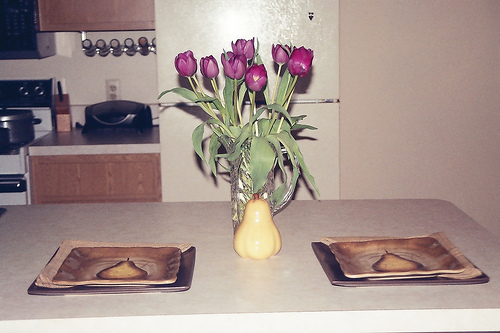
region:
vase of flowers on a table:
[166, 30, 318, 190]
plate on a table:
[301, 196, 491, 301]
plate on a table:
[30, 220, 208, 306]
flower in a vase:
[283, 35, 313, 85]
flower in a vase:
[246, 58, 271, 88]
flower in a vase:
[221, 46, 244, 84]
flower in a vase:
[195, 47, 225, 82]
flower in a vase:
[166, 45, 192, 75]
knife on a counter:
[45, 76, 72, 146]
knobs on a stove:
[11, 80, 49, 105]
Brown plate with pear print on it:
[34, 237, 196, 294]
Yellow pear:
[226, 190, 291, 259]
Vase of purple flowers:
[160, 31, 316, 257]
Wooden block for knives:
[53, 79, 75, 130]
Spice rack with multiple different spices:
[76, 28, 156, 55]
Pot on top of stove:
[0, 100, 41, 158]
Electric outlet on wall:
[103, 75, 121, 101]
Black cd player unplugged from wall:
[71, 99, 156, 138]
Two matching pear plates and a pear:
[30, 190, 493, 292]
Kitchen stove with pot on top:
[0, 75, 55, 207]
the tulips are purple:
[164, 28, 321, 103]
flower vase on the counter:
[175, 36, 337, 273]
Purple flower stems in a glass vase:
[157, 37, 321, 237]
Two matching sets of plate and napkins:
[25, 232, 489, 292]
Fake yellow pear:
[232, 191, 282, 261]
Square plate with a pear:
[51, 244, 181, 284]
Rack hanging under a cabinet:
[79, 32, 154, 57]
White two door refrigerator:
[150, 0, 343, 200]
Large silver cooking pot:
[0, 104, 41, 150]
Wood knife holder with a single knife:
[53, 80, 71, 133]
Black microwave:
[0, 1, 55, 62]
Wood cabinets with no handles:
[25, 0, 163, 202]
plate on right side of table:
[308, 225, 473, 286]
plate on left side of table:
[18, 220, 210, 309]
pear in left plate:
[101, 256, 151, 282]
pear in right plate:
[371, 245, 424, 270]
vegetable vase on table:
[229, 200, 285, 261]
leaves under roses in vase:
[228, 126, 288, 166]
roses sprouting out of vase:
[171, 30, 321, 96]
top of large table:
[141, 212, 190, 231]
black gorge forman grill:
[86, 102, 149, 131]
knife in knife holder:
[53, 79, 73, 136]